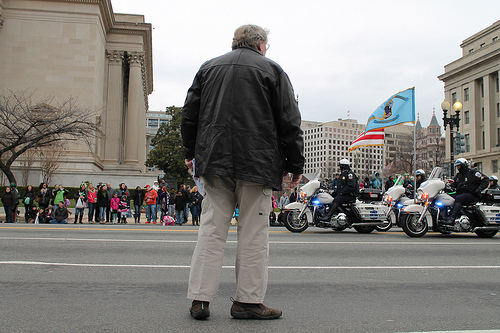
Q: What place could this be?
A: It is a street.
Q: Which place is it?
A: It is a street.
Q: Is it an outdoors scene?
A: Yes, it is outdoors.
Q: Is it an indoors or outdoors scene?
A: It is outdoors.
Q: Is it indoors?
A: No, it is outdoors.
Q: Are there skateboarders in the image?
A: No, there are no skateboarders.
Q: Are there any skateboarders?
A: No, there are no skateboarders.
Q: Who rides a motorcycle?
A: The man rides a motorcycle.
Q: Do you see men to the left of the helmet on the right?
A: Yes, there is a man to the left of the helmet.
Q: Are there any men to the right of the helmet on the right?
A: No, the man is to the left of the helmet.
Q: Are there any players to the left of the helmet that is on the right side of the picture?
A: No, there is a man to the left of the helmet.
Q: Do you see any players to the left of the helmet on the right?
A: No, there is a man to the left of the helmet.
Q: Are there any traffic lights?
A: No, there are no traffic lights.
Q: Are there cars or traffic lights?
A: No, there are no traffic lights or cars.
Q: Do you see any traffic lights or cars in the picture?
A: No, there are no traffic lights or cars.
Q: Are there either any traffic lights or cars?
A: No, there are no traffic lights or cars.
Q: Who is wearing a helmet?
A: The man is wearing a helmet.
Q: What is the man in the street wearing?
A: The man is wearing a helmet.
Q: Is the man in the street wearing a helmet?
A: Yes, the man is wearing a helmet.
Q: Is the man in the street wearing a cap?
A: No, the man is wearing a helmet.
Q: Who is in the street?
A: The man is in the street.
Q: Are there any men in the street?
A: Yes, there is a man in the street.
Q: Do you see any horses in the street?
A: No, there is a man in the street.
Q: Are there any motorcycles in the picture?
A: Yes, there is a motorcycle.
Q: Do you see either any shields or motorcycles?
A: Yes, there is a motorcycle.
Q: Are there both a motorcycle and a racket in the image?
A: No, there is a motorcycle but no rackets.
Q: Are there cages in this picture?
A: No, there are no cages.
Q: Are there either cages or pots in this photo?
A: No, there are no cages or pots.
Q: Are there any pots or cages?
A: No, there are no cages or pots.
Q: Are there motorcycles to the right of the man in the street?
A: Yes, there is a motorcycle to the right of the man.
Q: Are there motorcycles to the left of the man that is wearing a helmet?
A: No, the motorcycle is to the right of the man.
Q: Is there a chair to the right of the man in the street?
A: No, there is a motorcycle to the right of the man.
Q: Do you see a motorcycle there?
A: Yes, there is a motorcycle.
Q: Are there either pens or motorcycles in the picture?
A: Yes, there is a motorcycle.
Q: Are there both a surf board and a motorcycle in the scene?
A: No, there is a motorcycle but no surfboards.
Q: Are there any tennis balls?
A: No, there are no tennis balls.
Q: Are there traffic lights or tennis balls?
A: No, there are no tennis balls or traffic lights.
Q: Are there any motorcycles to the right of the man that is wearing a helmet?
A: Yes, there is a motorcycle to the right of the man.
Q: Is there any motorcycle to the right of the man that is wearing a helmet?
A: Yes, there is a motorcycle to the right of the man.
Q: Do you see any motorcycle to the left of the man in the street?
A: No, the motorcycle is to the right of the man.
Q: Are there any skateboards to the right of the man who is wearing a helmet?
A: No, there is a motorcycle to the right of the man.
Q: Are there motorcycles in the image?
A: Yes, there is a motorcycle.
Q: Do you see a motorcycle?
A: Yes, there is a motorcycle.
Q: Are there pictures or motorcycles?
A: Yes, there is a motorcycle.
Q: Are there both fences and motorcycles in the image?
A: No, there is a motorcycle but no fences.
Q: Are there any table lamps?
A: No, there are no table lamps.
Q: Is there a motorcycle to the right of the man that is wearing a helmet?
A: Yes, there is a motorcycle to the right of the man.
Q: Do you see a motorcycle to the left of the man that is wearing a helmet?
A: No, the motorcycle is to the right of the man.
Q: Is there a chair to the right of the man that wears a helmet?
A: No, there is a motorcycle to the right of the man.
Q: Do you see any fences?
A: No, there are no fences.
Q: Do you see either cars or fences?
A: No, there are no fences or cars.